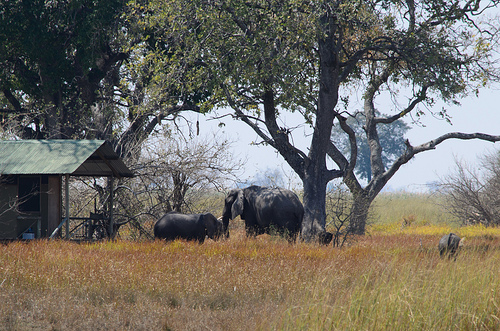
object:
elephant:
[223, 179, 304, 244]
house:
[0, 137, 123, 242]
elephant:
[153, 211, 220, 244]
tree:
[255, 30, 341, 237]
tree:
[300, 52, 414, 238]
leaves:
[295, 65, 301, 70]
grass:
[234, 283, 263, 297]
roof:
[0, 140, 131, 173]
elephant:
[438, 234, 461, 259]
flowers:
[204, 243, 211, 248]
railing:
[57, 214, 86, 223]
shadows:
[270, 195, 284, 205]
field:
[0, 242, 426, 331]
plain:
[396, 229, 435, 237]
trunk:
[301, 152, 329, 202]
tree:
[329, 182, 352, 250]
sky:
[454, 108, 490, 122]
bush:
[330, 198, 358, 250]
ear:
[230, 199, 245, 218]